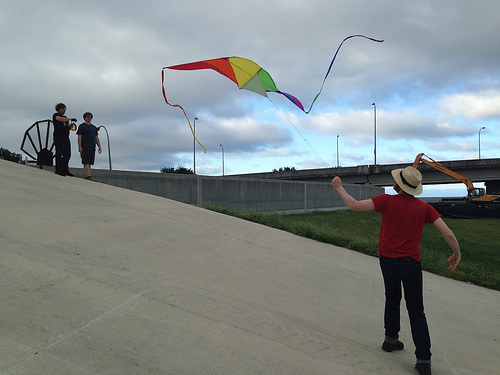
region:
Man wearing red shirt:
[318, 162, 473, 374]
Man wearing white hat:
[325, 159, 480, 371]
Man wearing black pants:
[327, 160, 469, 372]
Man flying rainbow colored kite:
[153, 31, 498, 312]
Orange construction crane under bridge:
[400, 139, 497, 215]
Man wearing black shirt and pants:
[48, 98, 76, 183]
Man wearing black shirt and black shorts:
[73, 106, 113, 182]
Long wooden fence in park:
[75, 165, 402, 226]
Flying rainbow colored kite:
[153, 32, 401, 149]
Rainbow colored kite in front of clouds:
[155, 32, 392, 154]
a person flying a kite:
[157, 32, 462, 374]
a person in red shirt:
[325, 162, 462, 372]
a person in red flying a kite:
[155, 30, 461, 371]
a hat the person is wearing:
[387, 162, 422, 193]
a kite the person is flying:
[151, 30, 383, 152]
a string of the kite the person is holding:
[270, 102, 345, 192]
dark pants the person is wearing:
[371, 253, 431, 363]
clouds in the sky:
[0, 0, 466, 156]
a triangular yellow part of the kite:
[225, 53, 260, 88]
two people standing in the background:
[50, 96, 105, 181]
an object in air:
[130, 30, 382, 130]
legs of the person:
[355, 276, 460, 373]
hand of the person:
[440, 225, 485, 287]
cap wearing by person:
[381, 143, 426, 195]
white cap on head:
[385, 166, 420, 206]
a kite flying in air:
[132, 35, 419, 173]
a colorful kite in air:
[158, 18, 352, 124]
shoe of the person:
[371, 328, 412, 356]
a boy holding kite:
[158, 40, 496, 373]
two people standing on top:
[22, 78, 123, 196]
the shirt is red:
[371, 187, 430, 262]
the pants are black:
[370, 255, 430, 345]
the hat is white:
[391, 166, 435, 200]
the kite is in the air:
[171, 46, 296, 123]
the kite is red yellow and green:
[168, 40, 290, 117]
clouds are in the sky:
[0, 2, 95, 91]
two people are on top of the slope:
[48, 102, 111, 177]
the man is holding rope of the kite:
[311, 154, 451, 374]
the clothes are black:
[73, 127, 99, 163]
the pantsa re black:
[53, 135, 73, 172]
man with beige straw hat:
[329, 155, 466, 374]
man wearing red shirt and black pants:
[331, 155, 465, 374]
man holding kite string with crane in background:
[303, 135, 496, 372]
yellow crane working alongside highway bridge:
[423, 150, 498, 202]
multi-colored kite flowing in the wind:
[158, 11, 380, 140]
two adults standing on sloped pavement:
[51, 102, 112, 191]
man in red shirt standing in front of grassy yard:
[339, 166, 436, 283]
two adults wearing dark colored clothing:
[52, 104, 109, 196]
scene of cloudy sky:
[403, 64, 470, 146]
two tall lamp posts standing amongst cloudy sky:
[333, 105, 381, 164]